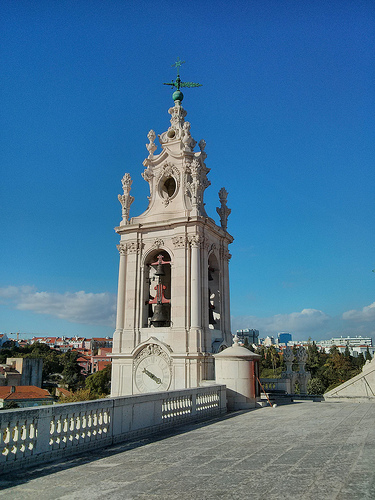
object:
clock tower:
[111, 54, 236, 396]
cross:
[162, 56, 203, 90]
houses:
[0, 384, 54, 407]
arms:
[142, 367, 164, 384]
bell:
[146, 255, 171, 327]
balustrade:
[0, 384, 228, 474]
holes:
[162, 395, 193, 420]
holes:
[1, 420, 38, 458]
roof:
[56, 387, 75, 397]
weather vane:
[162, 56, 203, 101]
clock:
[131, 335, 175, 395]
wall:
[110, 359, 131, 396]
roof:
[98, 361, 112, 371]